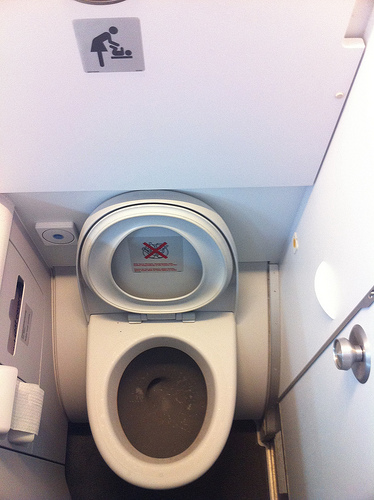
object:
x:
[142, 241, 168, 260]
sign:
[127, 235, 183, 273]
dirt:
[135, 370, 180, 421]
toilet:
[73, 187, 241, 494]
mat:
[64, 417, 272, 498]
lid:
[74, 187, 240, 326]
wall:
[0, 0, 373, 268]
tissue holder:
[0, 237, 47, 388]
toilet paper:
[8, 379, 45, 437]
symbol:
[70, 15, 145, 75]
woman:
[90, 24, 120, 68]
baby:
[109, 44, 133, 59]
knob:
[331, 322, 373, 385]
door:
[274, 132, 374, 499]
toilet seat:
[79, 202, 234, 315]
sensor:
[33, 220, 78, 248]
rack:
[0, 365, 45, 443]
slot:
[7, 273, 26, 357]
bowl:
[104, 332, 217, 470]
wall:
[0, 193, 75, 496]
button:
[292, 231, 299, 255]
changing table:
[0, 0, 374, 194]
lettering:
[133, 262, 177, 272]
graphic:
[90, 25, 134, 67]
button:
[52, 233, 63, 240]